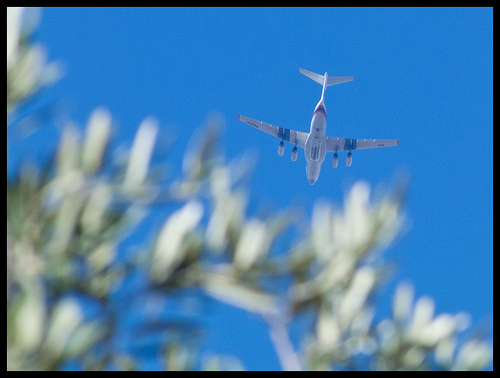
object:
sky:
[0, 9, 494, 371]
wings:
[236, 114, 309, 150]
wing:
[326, 137, 398, 150]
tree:
[150, 149, 402, 374]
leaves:
[45, 197, 79, 245]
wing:
[298, 69, 357, 89]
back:
[297, 66, 352, 113]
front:
[302, 139, 326, 187]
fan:
[273, 143, 283, 157]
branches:
[265, 326, 335, 370]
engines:
[276, 125, 288, 157]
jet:
[236, 67, 398, 185]